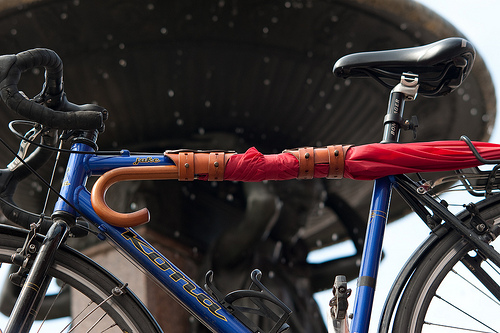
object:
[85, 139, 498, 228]
umbrella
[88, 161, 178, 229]
handle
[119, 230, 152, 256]
lettering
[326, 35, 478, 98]
seat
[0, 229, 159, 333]
tire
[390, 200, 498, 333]
tire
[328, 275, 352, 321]
pedal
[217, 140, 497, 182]
red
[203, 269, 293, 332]
holder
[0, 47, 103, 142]
handle bars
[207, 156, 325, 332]
statue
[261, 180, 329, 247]
head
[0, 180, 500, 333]
background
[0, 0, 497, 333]
structure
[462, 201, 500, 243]
brakes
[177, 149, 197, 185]
straps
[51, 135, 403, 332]
frame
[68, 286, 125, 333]
spokes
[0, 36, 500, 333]
bike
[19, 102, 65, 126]
tape